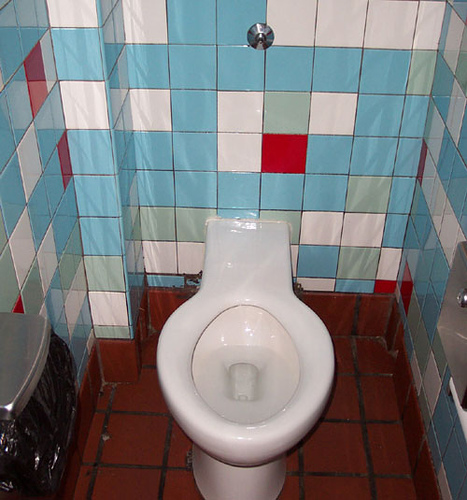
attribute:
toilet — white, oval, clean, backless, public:
[156, 216, 338, 500]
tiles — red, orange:
[55, 287, 441, 500]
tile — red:
[261, 133, 308, 176]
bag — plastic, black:
[1, 335, 77, 498]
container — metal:
[432, 241, 466, 408]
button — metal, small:
[244, 22, 275, 53]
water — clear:
[199, 342, 292, 420]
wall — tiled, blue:
[2, 3, 463, 496]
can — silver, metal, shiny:
[1, 313, 53, 411]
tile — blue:
[167, 42, 217, 91]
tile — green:
[262, 89, 312, 135]